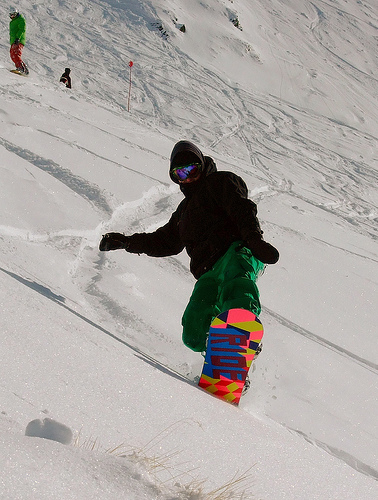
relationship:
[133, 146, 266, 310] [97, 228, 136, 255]
athletes in black gloves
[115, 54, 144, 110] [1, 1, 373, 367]
pole into snow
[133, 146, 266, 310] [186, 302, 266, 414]
athletes riding snow board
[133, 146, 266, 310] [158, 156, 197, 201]
athletes wearing goggles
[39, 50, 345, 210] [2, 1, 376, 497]
marks on snow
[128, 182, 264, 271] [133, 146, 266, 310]
black jacket on athletes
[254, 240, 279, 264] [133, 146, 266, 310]
mitten on athletes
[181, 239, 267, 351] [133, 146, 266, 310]
green pants on athletes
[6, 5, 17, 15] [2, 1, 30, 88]
helmet on athletes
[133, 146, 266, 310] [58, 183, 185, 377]
athletes on trail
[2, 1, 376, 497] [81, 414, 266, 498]
snow on grass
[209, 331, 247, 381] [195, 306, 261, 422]
word on snow board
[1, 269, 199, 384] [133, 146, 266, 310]
shadow by athletes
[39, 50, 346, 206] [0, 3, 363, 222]
marks in snow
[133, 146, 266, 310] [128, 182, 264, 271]
athletes in black jacket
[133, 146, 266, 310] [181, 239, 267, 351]
athletes in green pants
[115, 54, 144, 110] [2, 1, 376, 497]
pole in snow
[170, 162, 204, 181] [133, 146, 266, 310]
goggles on athletes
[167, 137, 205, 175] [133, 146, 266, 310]
hat on athletes